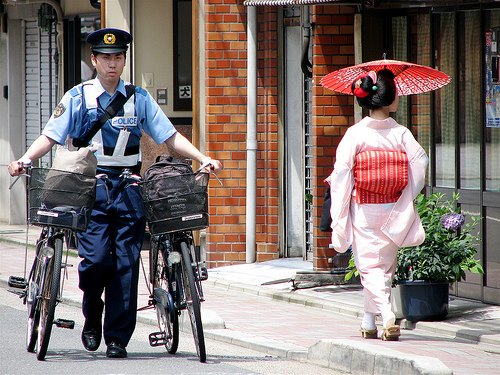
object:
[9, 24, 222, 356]
policeman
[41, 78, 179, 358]
uniform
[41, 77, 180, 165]
blue uniform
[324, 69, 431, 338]
woman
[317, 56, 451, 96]
red umbrella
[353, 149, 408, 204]
back pack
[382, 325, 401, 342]
clogs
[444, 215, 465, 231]
flower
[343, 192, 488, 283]
bush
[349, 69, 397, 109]
dark hair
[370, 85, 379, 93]
ornaments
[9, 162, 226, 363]
two bikes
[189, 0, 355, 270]
building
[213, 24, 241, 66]
brick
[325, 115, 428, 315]
kimono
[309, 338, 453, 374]
curb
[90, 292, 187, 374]
road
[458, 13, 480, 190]
windows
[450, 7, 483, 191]
brown frames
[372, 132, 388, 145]
pink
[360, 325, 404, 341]
pair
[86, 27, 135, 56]
hat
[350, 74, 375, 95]
intricate bun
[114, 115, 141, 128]
tag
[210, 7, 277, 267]
wall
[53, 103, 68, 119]
police badge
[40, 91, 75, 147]
sleeve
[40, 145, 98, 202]
bag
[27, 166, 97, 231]
basket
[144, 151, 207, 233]
bag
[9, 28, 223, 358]
man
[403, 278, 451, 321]
pot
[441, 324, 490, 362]
ground